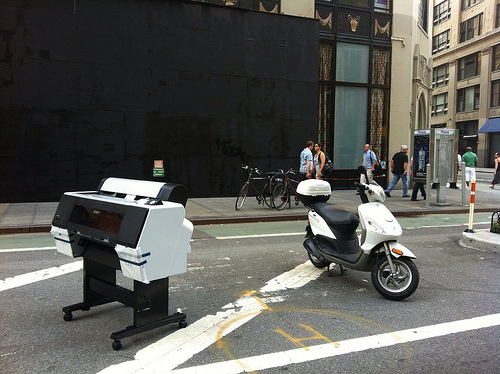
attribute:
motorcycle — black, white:
[295, 176, 417, 297]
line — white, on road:
[113, 306, 499, 372]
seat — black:
[316, 200, 357, 228]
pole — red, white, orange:
[469, 176, 475, 233]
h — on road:
[275, 321, 332, 353]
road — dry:
[5, 207, 500, 371]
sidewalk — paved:
[3, 184, 499, 228]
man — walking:
[389, 140, 408, 197]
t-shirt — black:
[391, 151, 405, 175]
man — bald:
[362, 144, 378, 181]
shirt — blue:
[361, 152, 376, 168]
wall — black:
[3, 1, 316, 200]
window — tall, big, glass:
[319, 38, 385, 169]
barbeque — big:
[49, 174, 193, 353]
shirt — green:
[462, 154, 475, 166]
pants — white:
[464, 167, 476, 185]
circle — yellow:
[210, 312, 411, 374]